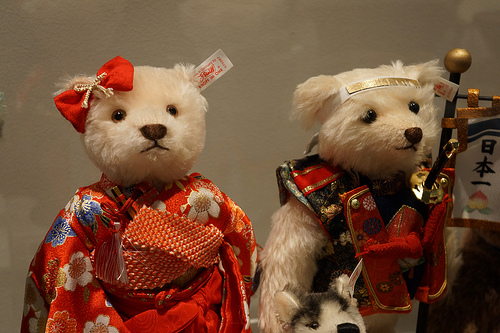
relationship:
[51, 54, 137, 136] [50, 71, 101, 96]
bow tied on ear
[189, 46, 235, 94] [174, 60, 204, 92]
tag on side of ear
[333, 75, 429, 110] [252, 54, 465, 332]
headband on top of bear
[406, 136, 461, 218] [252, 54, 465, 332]
sword worn on bear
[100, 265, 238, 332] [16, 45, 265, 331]
sash worn on bear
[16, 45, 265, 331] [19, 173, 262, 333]
bear inside of dress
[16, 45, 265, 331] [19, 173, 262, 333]
bear wearing dress